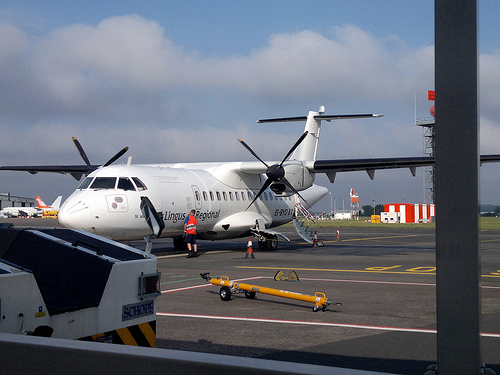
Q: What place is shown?
A: It is a runway.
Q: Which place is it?
A: It is a runway.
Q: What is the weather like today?
A: It is partly cloudy.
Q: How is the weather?
A: It is partly cloudy.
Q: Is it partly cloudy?
A: Yes, it is partly cloudy.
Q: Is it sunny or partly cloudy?
A: It is partly cloudy.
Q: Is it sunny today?
A: No, it is partly cloudy.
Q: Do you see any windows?
A: Yes, there is a window.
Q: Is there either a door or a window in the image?
A: Yes, there is a window.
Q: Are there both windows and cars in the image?
A: No, there is a window but no cars.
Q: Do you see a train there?
A: No, there are no trains.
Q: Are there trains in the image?
A: No, there are no trains.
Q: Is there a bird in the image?
A: No, there are no birds.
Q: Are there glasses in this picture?
A: No, there are no glasses.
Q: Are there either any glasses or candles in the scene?
A: No, there are no glasses or candles.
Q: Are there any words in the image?
A: Yes, there are words.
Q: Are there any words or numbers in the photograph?
A: Yes, there are words.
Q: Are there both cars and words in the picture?
A: No, there are words but no cars.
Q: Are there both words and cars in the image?
A: No, there are words but no cars.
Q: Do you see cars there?
A: No, there are no cars.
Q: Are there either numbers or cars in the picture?
A: No, there are no cars or numbers.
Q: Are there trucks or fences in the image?
A: No, there are no fences or trucks.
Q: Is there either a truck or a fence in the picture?
A: No, there are no fences or trucks.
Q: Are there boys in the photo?
A: No, there are no boys.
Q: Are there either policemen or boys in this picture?
A: No, there are no boys or policemen.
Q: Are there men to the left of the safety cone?
A: Yes, there is a man to the left of the safety cone.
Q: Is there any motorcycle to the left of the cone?
A: No, there is a man to the left of the cone.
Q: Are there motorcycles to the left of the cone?
A: No, there is a man to the left of the cone.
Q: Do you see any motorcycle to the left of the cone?
A: No, there is a man to the left of the cone.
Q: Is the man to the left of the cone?
A: Yes, the man is to the left of the cone.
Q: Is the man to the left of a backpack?
A: No, the man is to the left of the cone.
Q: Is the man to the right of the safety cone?
A: No, the man is to the left of the safety cone.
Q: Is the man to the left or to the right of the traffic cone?
A: The man is to the left of the traffic cone.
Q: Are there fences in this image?
A: No, there are no fences.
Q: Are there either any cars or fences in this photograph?
A: No, there are no fences or cars.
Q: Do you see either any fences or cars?
A: No, there are no fences or cars.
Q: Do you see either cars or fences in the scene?
A: No, there are no fences or cars.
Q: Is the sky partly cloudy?
A: Yes, the sky is partly cloudy.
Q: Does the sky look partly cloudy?
A: Yes, the sky is partly cloudy.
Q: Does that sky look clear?
A: No, the sky is partly cloudy.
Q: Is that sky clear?
A: No, the sky is partly cloudy.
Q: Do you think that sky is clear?
A: No, the sky is partly cloudy.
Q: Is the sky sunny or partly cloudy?
A: The sky is partly cloudy.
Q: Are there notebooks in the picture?
A: No, there are no notebooks.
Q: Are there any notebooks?
A: No, there are no notebooks.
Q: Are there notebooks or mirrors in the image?
A: No, there are no notebooks or mirrors.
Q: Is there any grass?
A: Yes, there is grass.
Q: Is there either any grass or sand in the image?
A: Yes, there is grass.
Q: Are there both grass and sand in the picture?
A: No, there is grass but no sand.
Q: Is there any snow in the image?
A: No, there is no snow.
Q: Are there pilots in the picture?
A: No, there are no pilots.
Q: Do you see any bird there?
A: No, there are no birds.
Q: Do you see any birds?
A: No, there are no birds.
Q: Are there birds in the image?
A: No, there are no birds.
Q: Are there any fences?
A: No, there are no fences.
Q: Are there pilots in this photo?
A: No, there are no pilots.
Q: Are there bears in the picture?
A: No, there are no bears.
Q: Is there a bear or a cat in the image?
A: No, there are no bears or cats.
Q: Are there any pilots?
A: No, there are no pilots.